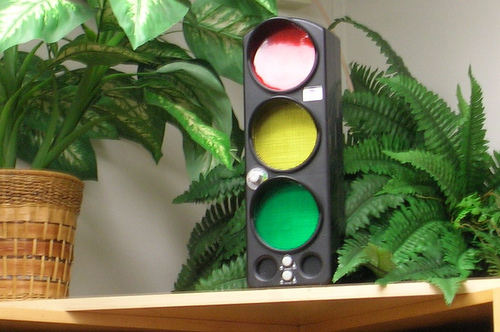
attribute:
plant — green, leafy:
[2, 0, 280, 182]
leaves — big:
[2, 0, 279, 182]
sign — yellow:
[244, 96, 318, 172]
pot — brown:
[0, 154, 92, 330]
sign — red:
[239, 15, 342, 289]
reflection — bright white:
[241, 37, 335, 101]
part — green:
[250, 179, 321, 248]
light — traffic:
[248, 95, 320, 171]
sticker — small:
[291, 87, 341, 110]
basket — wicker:
[0, 168, 102, 310]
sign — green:
[250, 175, 322, 251]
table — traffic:
[38, 268, 493, 323]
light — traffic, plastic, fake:
[240, 15, 338, 287]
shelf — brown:
[1, 276, 498, 330]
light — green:
[252, 184, 323, 252]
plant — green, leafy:
[344, 62, 484, 265]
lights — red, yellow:
[249, 23, 326, 253]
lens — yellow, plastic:
[250, 103, 319, 172]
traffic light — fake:
[239, 15, 338, 281]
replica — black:
[241, 18, 341, 283]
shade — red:
[243, 18, 320, 89]